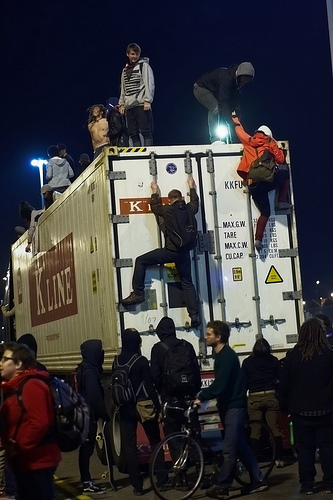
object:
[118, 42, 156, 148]
person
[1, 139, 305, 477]
truck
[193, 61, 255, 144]
person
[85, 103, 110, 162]
person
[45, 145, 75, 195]
person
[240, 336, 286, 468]
person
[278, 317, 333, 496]
person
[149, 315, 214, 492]
person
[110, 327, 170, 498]
person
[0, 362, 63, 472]
jacket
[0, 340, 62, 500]
person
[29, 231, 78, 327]
logo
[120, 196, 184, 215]
logo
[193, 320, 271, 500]
man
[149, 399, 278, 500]
bicycle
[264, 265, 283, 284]
hazard label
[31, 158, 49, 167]
light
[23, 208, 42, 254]
leg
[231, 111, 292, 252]
man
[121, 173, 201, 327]
man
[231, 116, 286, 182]
jacket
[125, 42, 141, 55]
hair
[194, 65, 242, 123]
jacket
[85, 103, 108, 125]
long hair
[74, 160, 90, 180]
shirt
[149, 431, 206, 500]
tire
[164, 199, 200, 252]
backpack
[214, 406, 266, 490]
jeans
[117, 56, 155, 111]
shirt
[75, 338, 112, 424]
jacket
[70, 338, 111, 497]
man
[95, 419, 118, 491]
skateboard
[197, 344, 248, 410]
shirt